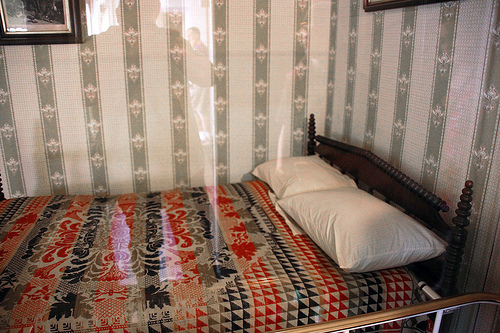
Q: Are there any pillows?
A: Yes, there is a pillow.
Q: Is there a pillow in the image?
A: Yes, there is a pillow.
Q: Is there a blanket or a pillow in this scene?
A: Yes, there is a pillow.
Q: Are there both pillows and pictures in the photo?
A: Yes, there are both a pillow and a picture.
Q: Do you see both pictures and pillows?
A: Yes, there are both a pillow and a picture.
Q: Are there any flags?
A: No, there are no flags.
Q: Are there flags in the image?
A: No, there are no flags.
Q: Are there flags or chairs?
A: No, there are no flags or chairs.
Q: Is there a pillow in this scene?
A: Yes, there is a pillow.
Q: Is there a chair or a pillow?
A: Yes, there is a pillow.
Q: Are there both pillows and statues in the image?
A: No, there is a pillow but no statues.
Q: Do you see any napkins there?
A: No, there are no napkins.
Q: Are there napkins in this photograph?
A: No, there are no napkins.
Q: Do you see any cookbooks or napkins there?
A: No, there are no napkins or cookbooks.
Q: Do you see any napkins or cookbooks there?
A: No, there are no napkins or cookbooks.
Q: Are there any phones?
A: No, there are no phones.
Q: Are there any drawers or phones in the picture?
A: No, there are no phones or drawers.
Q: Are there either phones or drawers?
A: No, there are no phones or drawers.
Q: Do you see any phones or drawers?
A: No, there are no phones or drawers.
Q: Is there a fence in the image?
A: No, there are no fences.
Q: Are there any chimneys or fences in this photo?
A: No, there are no fences or chimneys.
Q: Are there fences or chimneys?
A: No, there are no fences or chimneys.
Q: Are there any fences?
A: No, there are no fences.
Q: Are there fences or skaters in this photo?
A: No, there are no fences or skaters.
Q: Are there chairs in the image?
A: No, there are no chairs.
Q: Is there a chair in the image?
A: No, there are no chairs.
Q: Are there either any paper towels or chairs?
A: No, there are no chairs or paper towels.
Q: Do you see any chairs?
A: No, there are no chairs.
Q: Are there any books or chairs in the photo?
A: No, there are no chairs or books.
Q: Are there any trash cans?
A: No, there are no trash cans.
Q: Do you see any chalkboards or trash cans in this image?
A: No, there are no trash cans or chalkboards.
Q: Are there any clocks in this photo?
A: No, there are no clocks.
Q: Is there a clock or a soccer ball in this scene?
A: No, there are no clocks or soccer balls.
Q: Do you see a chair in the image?
A: No, there are no chairs.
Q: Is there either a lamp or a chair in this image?
A: No, there are no chairs or lamps.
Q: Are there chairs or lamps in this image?
A: No, there are no chairs or lamps.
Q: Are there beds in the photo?
A: Yes, there is a bed.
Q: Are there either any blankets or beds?
A: Yes, there is a bed.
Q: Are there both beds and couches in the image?
A: No, there is a bed but no couches.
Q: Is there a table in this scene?
A: No, there are no tables.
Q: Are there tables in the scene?
A: No, there are no tables.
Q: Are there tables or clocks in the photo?
A: No, there are no tables or clocks.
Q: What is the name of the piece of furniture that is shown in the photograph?
A: The piece of furniture is a bed.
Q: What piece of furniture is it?
A: The piece of furniture is a bed.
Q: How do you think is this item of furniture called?
A: That is a bed.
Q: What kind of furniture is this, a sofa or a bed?
A: That is a bed.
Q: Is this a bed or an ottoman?
A: This is a bed.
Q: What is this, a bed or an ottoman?
A: This is a bed.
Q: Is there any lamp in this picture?
A: No, there are no lamps.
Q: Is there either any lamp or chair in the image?
A: No, there are no lamps or chairs.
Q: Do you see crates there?
A: No, there are no crates.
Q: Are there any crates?
A: No, there are no crates.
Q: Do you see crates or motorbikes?
A: No, there are no crates or motorbikes.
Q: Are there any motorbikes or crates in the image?
A: No, there are no crates or motorbikes.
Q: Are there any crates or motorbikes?
A: No, there are no crates or motorbikes.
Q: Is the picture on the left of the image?
A: Yes, the picture is on the left of the image.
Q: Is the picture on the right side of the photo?
A: No, the picture is on the left of the image.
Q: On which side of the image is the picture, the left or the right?
A: The picture is on the left of the image.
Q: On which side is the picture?
A: The picture is on the left of the image.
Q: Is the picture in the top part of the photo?
A: Yes, the picture is in the top of the image.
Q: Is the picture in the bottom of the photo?
A: No, the picture is in the top of the image.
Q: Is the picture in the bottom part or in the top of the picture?
A: The picture is in the top of the image.